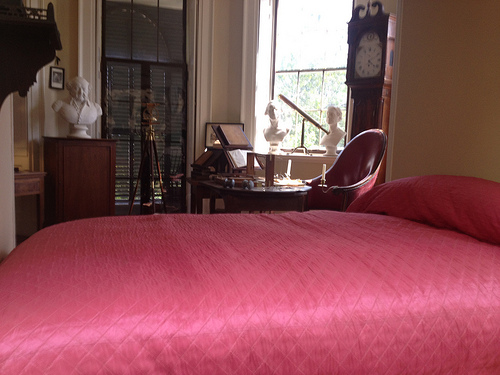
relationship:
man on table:
[48, 73, 106, 138] [49, 137, 114, 217]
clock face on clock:
[348, 33, 393, 92] [347, 27, 386, 89]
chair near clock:
[303, 127, 391, 209] [347, 27, 386, 89]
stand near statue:
[36, 113, 131, 237] [58, 81, 101, 141]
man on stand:
[48, 73, 106, 138] [36, 136, 124, 228]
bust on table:
[57, 79, 102, 135] [49, 137, 114, 217]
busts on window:
[257, 93, 352, 160] [246, 38, 344, 154]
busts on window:
[257, 93, 352, 160] [258, 1, 343, 155]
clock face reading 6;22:
[348, 33, 398, 92] [359, 57, 383, 78]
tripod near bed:
[124, 107, 170, 207] [1, 175, 498, 374]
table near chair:
[200, 171, 323, 217] [308, 126, 388, 209]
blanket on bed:
[0, 204, 475, 368] [1, 175, 498, 374]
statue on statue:
[316, 98, 343, 158] [316, 98, 343, 158]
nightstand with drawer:
[15, 171, 49, 237] [13, 175, 42, 200]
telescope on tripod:
[134, 95, 169, 202] [124, 120, 174, 213]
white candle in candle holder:
[322, 162, 327, 179] [315, 177, 328, 187]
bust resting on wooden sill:
[316, 103, 346, 155] [251, 150, 341, 167]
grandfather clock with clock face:
[343, 0, 398, 187] [348, 33, 393, 92]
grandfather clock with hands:
[343, 0, 398, 187] [365, 59, 378, 70]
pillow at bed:
[344, 165, 496, 243] [1, 175, 498, 374]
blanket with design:
[0, 204, 475, 368] [52, 220, 239, 310]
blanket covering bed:
[0, 204, 475, 368] [1, 175, 498, 374]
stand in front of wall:
[12, 165, 46, 245] [403, 29, 480, 143]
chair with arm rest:
[303, 127, 386, 211] [322, 172, 373, 211]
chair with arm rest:
[303, 127, 386, 211] [297, 164, 333, 204]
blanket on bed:
[0, 171, 484, 369] [6, 151, 484, 361]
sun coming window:
[247, 9, 347, 149] [244, 2, 355, 148]